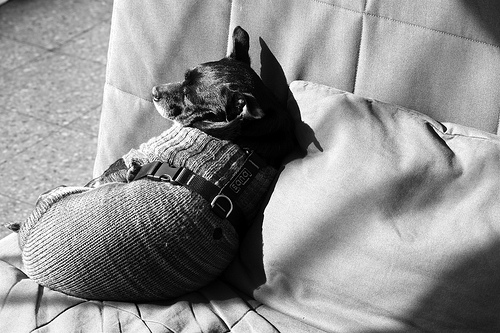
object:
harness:
[96, 150, 240, 225]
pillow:
[251, 76, 500, 333]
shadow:
[232, 35, 341, 209]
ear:
[229, 24, 252, 62]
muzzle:
[138, 73, 178, 113]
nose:
[140, 71, 202, 120]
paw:
[89, 148, 154, 209]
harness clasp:
[134, 159, 207, 190]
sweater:
[16, 122, 287, 309]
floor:
[0, 0, 114, 244]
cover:
[10, 102, 449, 312]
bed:
[87, 24, 478, 284]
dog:
[4, 24, 324, 306]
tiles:
[10, 24, 80, 177]